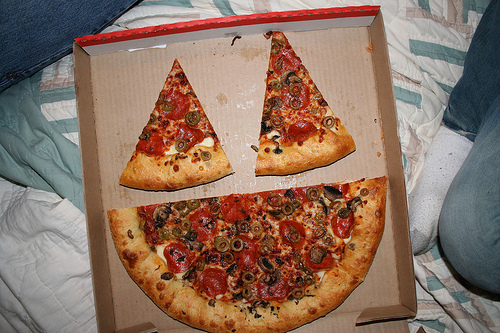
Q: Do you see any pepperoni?
A: Yes, there is pepperoni.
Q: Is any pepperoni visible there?
A: Yes, there is pepperoni.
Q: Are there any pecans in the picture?
A: No, there are no pecans.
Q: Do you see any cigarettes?
A: No, there are no cigarettes.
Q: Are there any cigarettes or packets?
A: No, there are no cigarettes or packets.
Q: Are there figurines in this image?
A: No, there are no figurines.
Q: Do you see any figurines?
A: No, there are no figurines.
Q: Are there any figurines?
A: No, there are no figurines.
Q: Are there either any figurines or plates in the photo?
A: No, there are no figurines or plates.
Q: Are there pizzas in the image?
A: Yes, there is a pizza.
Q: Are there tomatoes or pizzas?
A: Yes, there is a pizza.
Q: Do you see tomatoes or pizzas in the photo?
A: Yes, there is a pizza.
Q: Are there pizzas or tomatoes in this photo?
A: Yes, there is a pizza.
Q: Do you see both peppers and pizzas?
A: No, there is a pizza but no peppers.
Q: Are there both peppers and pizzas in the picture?
A: No, there is a pizza but no peppers.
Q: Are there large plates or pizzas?
A: Yes, there is a large pizza.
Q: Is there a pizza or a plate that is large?
A: Yes, the pizza is large.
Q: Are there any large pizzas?
A: Yes, there is a large pizza.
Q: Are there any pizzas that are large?
A: Yes, there is a pizza that is large.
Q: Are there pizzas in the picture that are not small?
A: Yes, there is a large pizza.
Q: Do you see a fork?
A: No, there are no forks.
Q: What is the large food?
A: The food is a pizza.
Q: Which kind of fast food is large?
A: The fast food is a pizza.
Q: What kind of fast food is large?
A: The fast food is a pizza.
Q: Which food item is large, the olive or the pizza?
A: The pizza is large.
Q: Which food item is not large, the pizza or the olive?
A: The olive is not large.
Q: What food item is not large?
A: The food item is an olive.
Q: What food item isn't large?
A: The food item is an olive.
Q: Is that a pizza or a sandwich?
A: That is a pizza.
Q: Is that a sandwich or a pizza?
A: That is a pizza.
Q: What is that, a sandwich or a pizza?
A: That is a pizza.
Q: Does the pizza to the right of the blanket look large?
A: Yes, the pizza is large.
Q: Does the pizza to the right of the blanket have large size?
A: Yes, the pizza is large.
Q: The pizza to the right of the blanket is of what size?
A: The pizza is large.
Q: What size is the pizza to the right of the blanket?
A: The pizza is large.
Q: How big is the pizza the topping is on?
A: The pizza is large.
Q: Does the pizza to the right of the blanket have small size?
A: No, the pizza is large.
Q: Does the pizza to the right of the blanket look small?
A: No, the pizza is large.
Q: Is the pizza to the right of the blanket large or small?
A: The pizza is large.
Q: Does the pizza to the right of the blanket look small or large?
A: The pizza is large.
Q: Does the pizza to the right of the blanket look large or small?
A: The pizza is large.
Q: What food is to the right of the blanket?
A: The food is a pizza.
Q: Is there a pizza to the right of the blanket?
A: Yes, there is a pizza to the right of the blanket.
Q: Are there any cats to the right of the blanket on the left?
A: No, there is a pizza to the right of the blanket.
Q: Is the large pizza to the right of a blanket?
A: Yes, the pizza is to the right of a blanket.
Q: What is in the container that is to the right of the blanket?
A: The pizza is in the box.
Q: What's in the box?
A: The pizza is in the box.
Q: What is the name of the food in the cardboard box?
A: The food is a pizza.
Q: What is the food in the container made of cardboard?
A: The food is a pizza.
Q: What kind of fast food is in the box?
A: The food is a pizza.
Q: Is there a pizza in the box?
A: Yes, there is a pizza in the box.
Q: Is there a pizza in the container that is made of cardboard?
A: Yes, there is a pizza in the box.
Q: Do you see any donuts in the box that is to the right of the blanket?
A: No, there is a pizza in the box.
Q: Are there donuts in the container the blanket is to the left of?
A: No, there is a pizza in the box.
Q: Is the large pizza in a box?
A: Yes, the pizza is in a box.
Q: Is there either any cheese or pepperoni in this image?
A: Yes, there is pepperoni.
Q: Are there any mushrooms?
A: No, there are no mushrooms.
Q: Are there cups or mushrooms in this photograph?
A: No, there are no mushrooms or cups.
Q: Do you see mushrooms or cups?
A: No, there are no mushrooms or cups.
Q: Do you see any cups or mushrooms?
A: No, there are no mushrooms or cups.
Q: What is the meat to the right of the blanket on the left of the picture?
A: The meat is pepperoni.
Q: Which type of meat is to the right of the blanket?
A: The meat is pepperoni.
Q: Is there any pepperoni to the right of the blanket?
A: Yes, there is pepperoni to the right of the blanket.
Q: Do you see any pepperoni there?
A: Yes, there is pepperoni.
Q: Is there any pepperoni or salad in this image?
A: Yes, there is pepperoni.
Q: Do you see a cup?
A: No, there are no cups.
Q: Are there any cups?
A: No, there are no cups.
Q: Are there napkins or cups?
A: No, there are no cups or napkins.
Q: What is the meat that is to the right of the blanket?
A: The meat is pepperoni.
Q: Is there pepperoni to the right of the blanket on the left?
A: Yes, there is pepperoni to the right of the blanket.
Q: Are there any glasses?
A: No, there are no glasses.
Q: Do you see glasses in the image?
A: No, there are no glasses.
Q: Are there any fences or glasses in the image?
A: No, there are no glasses or fences.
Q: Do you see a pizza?
A: Yes, there is a pizza.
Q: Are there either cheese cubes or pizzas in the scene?
A: Yes, there is a pizza.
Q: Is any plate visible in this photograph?
A: No, there are no plates.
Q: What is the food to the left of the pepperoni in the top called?
A: The food is a pizza.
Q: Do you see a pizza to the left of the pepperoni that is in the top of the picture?
A: Yes, there is a pizza to the left of the pepperoni.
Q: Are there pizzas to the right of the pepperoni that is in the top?
A: No, the pizza is to the left of the pepperoni.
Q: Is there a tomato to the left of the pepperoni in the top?
A: No, there is a pizza to the left of the pepperoni.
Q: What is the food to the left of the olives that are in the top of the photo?
A: The food is a pizza.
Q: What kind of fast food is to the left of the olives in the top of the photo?
A: The food is a pizza.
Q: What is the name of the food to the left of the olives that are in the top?
A: The food is a pizza.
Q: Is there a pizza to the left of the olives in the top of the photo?
A: Yes, there is a pizza to the left of the olives.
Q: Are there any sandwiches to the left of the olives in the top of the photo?
A: No, there is a pizza to the left of the olives.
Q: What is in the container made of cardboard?
A: The pizza is in the box.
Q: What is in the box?
A: The pizza is in the box.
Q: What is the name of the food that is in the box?
A: The food is a pizza.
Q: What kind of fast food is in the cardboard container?
A: The food is a pizza.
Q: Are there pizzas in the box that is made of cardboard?
A: Yes, there is a pizza in the box.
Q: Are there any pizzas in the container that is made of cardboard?
A: Yes, there is a pizza in the box.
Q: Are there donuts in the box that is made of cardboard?
A: No, there is a pizza in the box.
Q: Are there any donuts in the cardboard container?
A: No, there is a pizza in the box.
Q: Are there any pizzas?
A: Yes, there is a pizza.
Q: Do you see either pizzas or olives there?
A: Yes, there is a pizza.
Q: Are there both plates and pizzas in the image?
A: No, there is a pizza but no plates.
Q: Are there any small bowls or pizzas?
A: Yes, there is a small pizza.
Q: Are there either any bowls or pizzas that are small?
A: Yes, the pizza is small.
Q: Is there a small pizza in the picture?
A: Yes, there is a small pizza.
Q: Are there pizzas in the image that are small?
A: Yes, there is a pizza that is small.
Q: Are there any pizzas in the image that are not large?
A: Yes, there is a small pizza.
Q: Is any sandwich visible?
A: No, there are no sandwiches.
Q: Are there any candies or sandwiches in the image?
A: No, there are no sandwiches or candies.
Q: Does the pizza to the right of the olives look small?
A: Yes, the pizza is small.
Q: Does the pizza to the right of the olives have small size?
A: Yes, the pizza is small.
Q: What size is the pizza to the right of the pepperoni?
A: The pizza is small.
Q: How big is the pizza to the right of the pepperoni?
A: The pizza is small.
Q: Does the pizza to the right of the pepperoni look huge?
A: No, the pizza is small.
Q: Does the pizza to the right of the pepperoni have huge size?
A: No, the pizza is small.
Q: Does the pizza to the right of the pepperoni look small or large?
A: The pizza is small.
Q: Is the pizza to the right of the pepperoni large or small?
A: The pizza is small.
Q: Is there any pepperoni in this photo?
A: Yes, there is pepperoni.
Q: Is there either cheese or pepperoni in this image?
A: Yes, there is pepperoni.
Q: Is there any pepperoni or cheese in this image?
A: Yes, there is pepperoni.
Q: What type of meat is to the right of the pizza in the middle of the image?
A: The meat is pepperoni.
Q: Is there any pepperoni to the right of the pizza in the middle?
A: Yes, there is pepperoni to the right of the pizza.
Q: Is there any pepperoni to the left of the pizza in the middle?
A: No, the pepperoni is to the right of the pizza.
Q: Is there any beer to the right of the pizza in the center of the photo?
A: No, there is pepperoni to the right of the pizza.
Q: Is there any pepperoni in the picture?
A: Yes, there is pepperoni.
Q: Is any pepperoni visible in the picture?
A: Yes, there is pepperoni.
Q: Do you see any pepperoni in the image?
A: Yes, there is pepperoni.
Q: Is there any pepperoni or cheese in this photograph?
A: Yes, there is pepperoni.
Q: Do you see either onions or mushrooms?
A: No, there are no mushrooms or onions.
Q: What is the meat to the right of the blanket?
A: The meat is pepperoni.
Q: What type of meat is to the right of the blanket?
A: The meat is pepperoni.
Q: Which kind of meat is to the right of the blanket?
A: The meat is pepperoni.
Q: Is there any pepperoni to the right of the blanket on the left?
A: Yes, there is pepperoni to the right of the blanket.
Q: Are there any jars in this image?
A: No, there are no jars.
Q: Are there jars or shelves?
A: No, there are no jars or shelves.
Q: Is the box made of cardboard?
A: Yes, the box is made of cardboard.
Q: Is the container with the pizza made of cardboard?
A: Yes, the box is made of cardboard.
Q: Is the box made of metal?
A: No, the box is made of cardboard.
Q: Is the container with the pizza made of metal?
A: No, the box is made of cardboard.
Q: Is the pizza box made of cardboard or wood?
A: The box is made of cardboard.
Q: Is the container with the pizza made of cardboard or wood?
A: The box is made of cardboard.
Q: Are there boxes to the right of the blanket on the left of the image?
A: Yes, there is a box to the right of the blanket.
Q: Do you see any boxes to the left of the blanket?
A: No, the box is to the right of the blanket.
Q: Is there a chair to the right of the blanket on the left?
A: No, there is a box to the right of the blanket.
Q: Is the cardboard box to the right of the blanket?
A: Yes, the box is to the right of the blanket.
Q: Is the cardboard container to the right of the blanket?
A: Yes, the box is to the right of the blanket.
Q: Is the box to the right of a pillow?
A: No, the box is to the right of the blanket.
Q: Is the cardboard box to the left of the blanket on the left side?
A: No, the box is to the right of the blanket.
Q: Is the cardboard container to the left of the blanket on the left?
A: No, the box is to the right of the blanket.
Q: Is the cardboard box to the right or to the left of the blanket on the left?
A: The box is to the right of the blanket.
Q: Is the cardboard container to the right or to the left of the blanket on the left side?
A: The box is to the right of the blanket.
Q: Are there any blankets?
A: Yes, there is a blanket.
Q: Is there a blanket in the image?
A: Yes, there is a blanket.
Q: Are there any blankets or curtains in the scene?
A: Yes, there is a blanket.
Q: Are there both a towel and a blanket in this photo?
A: No, there is a blanket but no towels.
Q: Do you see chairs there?
A: No, there are no chairs.